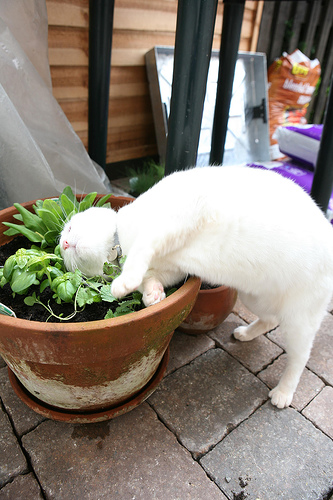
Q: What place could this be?
A: It is a sidewalk.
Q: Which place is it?
A: It is a sidewalk.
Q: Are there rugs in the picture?
A: No, there are no rugs.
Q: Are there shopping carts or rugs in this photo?
A: No, there are no rugs or shopping carts.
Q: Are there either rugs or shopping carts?
A: No, there are no rugs or shopping carts.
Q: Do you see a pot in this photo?
A: Yes, there is a pot.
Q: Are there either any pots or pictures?
A: Yes, there is a pot.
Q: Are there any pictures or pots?
A: Yes, there is a pot.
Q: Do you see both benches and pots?
A: No, there is a pot but no benches.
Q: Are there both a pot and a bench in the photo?
A: No, there is a pot but no benches.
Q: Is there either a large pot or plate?
A: Yes, there is a large pot.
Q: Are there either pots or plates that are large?
A: Yes, the pot is large.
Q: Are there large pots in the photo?
A: Yes, there is a large pot.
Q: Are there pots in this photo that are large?
A: Yes, there is a pot that is large.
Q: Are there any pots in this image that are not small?
A: Yes, there is a large pot.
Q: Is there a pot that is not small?
A: Yes, there is a large pot.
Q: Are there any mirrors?
A: No, there are no mirrors.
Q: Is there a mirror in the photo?
A: No, there are no mirrors.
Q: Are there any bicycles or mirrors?
A: No, there are no mirrors or bicycles.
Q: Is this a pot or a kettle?
A: This is a pot.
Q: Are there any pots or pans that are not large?
A: No, there is a pot but it is large.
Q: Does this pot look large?
A: Yes, the pot is large.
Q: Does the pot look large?
A: Yes, the pot is large.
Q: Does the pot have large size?
A: Yes, the pot is large.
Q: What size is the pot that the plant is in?
A: The pot is large.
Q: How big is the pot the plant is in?
A: The pot is large.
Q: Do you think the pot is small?
A: No, the pot is large.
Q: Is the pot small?
A: No, the pot is large.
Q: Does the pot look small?
A: No, the pot is large.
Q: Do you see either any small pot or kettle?
A: No, there is a pot but it is large.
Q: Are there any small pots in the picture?
A: No, there is a pot but it is large.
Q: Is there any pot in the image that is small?
A: No, there is a pot but it is large.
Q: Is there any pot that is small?
A: No, there is a pot but it is large.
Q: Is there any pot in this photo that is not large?
A: No, there is a pot but it is large.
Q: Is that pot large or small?
A: The pot is large.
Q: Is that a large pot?
A: Yes, that is a large pot.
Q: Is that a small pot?
A: No, that is a large pot.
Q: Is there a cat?
A: Yes, there is a cat.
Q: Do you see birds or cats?
A: Yes, there is a cat.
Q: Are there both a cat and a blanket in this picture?
A: No, there is a cat but no blankets.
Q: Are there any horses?
A: No, there are no horses.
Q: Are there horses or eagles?
A: No, there are no horses or eagles.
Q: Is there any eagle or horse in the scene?
A: No, there are no horses or eagles.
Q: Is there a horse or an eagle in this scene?
A: No, there are no horses or eagles.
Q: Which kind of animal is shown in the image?
A: The animal is a cat.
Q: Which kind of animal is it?
A: The animal is a cat.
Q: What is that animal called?
A: That is a cat.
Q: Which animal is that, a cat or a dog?
A: That is a cat.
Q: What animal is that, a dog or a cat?
A: That is a cat.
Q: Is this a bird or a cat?
A: This is a cat.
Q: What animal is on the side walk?
A: The cat is on the side walk.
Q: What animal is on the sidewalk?
A: The cat is on the side walk.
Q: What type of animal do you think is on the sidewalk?
A: The animal is a cat.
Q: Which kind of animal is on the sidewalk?
A: The animal is a cat.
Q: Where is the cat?
A: The cat is on the sidewalk.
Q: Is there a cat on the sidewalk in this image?
A: Yes, there is a cat on the sidewalk.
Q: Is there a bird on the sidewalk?
A: No, there is a cat on the sidewalk.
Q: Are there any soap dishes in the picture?
A: No, there are no soap dishes.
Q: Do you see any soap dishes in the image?
A: No, there are no soap dishes.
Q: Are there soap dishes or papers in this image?
A: No, there are no soap dishes or papers.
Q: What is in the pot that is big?
A: The plant is in the pot.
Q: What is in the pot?
A: The plant is in the pot.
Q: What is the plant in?
A: The plant is in the pot.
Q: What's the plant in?
A: The plant is in the pot.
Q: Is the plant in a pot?
A: Yes, the plant is in a pot.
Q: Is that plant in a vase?
A: No, the plant is in a pot.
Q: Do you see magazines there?
A: No, there are no magazines.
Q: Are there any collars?
A: Yes, there is a collar.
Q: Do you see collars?
A: Yes, there is a collar.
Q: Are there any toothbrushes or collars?
A: Yes, there is a collar.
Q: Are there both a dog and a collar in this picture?
A: No, there is a collar but no dogs.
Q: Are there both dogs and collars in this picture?
A: No, there is a collar but no dogs.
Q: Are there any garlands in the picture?
A: No, there are no garlands.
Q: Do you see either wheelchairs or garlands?
A: No, there are no garlands or wheelchairs.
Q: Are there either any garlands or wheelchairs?
A: No, there are no garlands or wheelchairs.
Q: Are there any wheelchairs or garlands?
A: No, there are no garlands or wheelchairs.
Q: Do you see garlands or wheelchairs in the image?
A: No, there are no garlands or wheelchairs.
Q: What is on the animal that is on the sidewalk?
A: The collar is on the cat.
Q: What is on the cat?
A: The collar is on the cat.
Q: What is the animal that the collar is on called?
A: The animal is a cat.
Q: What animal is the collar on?
A: The collar is on the cat.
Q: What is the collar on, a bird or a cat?
A: The collar is on a cat.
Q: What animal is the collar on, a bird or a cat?
A: The collar is on a cat.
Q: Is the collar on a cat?
A: Yes, the collar is on a cat.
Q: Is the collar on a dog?
A: No, the collar is on a cat.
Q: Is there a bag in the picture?
A: Yes, there is a bag.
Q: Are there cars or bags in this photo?
A: Yes, there is a bag.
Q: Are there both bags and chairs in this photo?
A: No, there is a bag but no chairs.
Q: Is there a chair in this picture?
A: No, there are no chairs.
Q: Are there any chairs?
A: No, there are no chairs.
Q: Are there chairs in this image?
A: No, there are no chairs.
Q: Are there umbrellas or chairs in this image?
A: No, there are no chairs or umbrellas.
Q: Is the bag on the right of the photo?
A: Yes, the bag is on the right of the image.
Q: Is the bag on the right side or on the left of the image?
A: The bag is on the right of the image.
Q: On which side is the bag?
A: The bag is on the right of the image.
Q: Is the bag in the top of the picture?
A: Yes, the bag is in the top of the image.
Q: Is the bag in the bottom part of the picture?
A: No, the bag is in the top of the image.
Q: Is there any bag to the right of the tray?
A: Yes, there is a bag to the right of the tray.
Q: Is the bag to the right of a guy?
A: No, the bag is to the right of the tray.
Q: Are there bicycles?
A: No, there are no bicycles.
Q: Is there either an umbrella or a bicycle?
A: No, there are no bicycles or umbrellas.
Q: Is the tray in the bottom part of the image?
A: No, the tray is in the top of the image.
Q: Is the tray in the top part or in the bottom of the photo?
A: The tray is in the top of the image.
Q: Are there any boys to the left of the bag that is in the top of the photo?
A: No, there is a tray to the left of the bag.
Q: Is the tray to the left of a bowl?
A: No, the tray is to the left of a bag.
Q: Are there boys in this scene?
A: No, there are no boys.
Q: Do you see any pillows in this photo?
A: No, there are no pillows.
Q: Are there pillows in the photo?
A: No, there are no pillows.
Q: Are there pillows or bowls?
A: No, there are no pillows or bowls.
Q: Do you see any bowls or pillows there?
A: No, there are no pillows or bowls.